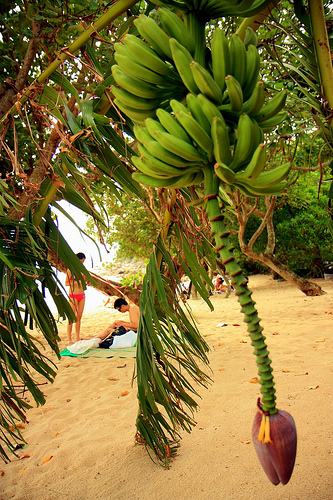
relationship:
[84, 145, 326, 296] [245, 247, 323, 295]
tree has a trunk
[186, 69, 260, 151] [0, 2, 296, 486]
bananas on tree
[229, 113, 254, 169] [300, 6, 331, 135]
bananas on tree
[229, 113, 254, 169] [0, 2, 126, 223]
bananas on tree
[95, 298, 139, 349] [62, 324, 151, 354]
guy sitting on blanket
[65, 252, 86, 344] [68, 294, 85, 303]
girl in bikini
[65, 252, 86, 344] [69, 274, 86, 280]
girl in bikini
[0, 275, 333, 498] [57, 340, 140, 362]
groves sand on blanket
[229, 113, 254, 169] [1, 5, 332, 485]
bananas are on tree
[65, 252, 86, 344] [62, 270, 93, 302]
girl wearing a bikini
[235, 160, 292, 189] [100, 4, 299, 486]
banana in a tree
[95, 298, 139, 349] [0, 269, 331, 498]
guy sitting in sand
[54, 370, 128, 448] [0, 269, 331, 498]
groves sand in sand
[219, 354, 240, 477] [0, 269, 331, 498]
groves in sand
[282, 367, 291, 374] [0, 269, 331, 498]
groves in sand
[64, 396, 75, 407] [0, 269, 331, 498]
grove in sand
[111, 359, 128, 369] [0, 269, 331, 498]
grove in sand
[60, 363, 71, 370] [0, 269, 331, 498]
grove in sand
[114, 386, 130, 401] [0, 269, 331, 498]
grove in sand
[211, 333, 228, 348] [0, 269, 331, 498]
grove in sand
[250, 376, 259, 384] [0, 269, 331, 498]
groves in sand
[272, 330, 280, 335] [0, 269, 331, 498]
groves in sand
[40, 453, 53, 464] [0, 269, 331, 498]
groves in sand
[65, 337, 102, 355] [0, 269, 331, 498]
towel sitting on sand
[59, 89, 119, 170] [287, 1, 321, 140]
leaves on tree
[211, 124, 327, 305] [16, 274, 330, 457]
tree sticking out sand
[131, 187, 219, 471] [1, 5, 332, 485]
banana leaf on tree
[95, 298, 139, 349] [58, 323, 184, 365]
guy sitting blanket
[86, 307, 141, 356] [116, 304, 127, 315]
guy wearing sunglasses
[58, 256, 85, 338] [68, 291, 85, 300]
girl wearing bikini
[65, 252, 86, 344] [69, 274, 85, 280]
girl wearing bikini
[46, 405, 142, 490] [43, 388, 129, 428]
groves in sand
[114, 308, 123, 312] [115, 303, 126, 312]
sunglasses on man's face